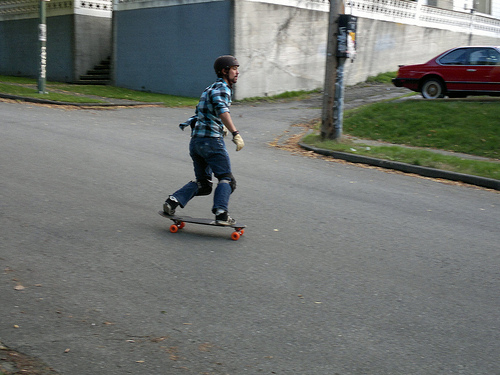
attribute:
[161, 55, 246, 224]
man — skateboarding, standing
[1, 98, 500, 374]
road — asphalt, gray, paved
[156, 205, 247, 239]
skateboard — black, red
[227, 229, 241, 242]
wheel — red, orange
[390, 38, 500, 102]
car — parked, red, compact, a sedan, in a parking lot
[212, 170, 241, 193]
kneepad — black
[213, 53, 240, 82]
helmet — black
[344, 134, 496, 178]
sidewalk — concrete, gray, grey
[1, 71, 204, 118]
grass — green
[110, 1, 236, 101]
wall — concrete, grey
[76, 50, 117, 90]
stairs — in a set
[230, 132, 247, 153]
glove — brown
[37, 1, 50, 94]
pole — tall, metal, grey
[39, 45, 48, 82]
writing — white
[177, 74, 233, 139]
shirt — plaid, white, blue, checkered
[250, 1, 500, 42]
rail — long, white